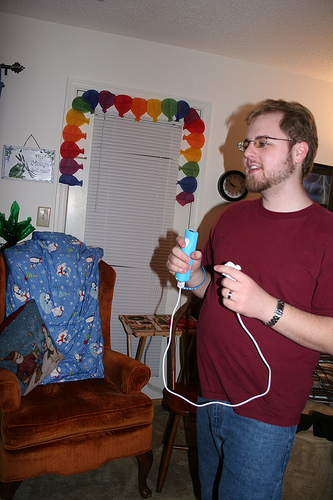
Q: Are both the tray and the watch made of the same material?
A: No, the tray is made of wood and the watch is made of metal.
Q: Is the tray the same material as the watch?
A: No, the tray is made of wood and the watch is made of metal.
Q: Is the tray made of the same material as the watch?
A: No, the tray is made of wood and the watch is made of metal.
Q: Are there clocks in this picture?
A: Yes, there is a clock.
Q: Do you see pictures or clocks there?
A: Yes, there is a clock.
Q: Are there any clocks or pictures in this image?
A: Yes, there is a clock.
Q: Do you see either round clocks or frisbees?
A: Yes, there is a round clock.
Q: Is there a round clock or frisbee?
A: Yes, there is a round clock.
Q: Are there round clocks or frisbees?
A: Yes, there is a round clock.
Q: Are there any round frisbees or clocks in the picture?
A: Yes, there is a round clock.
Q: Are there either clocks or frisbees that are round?
A: Yes, the clock is round.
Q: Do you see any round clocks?
A: Yes, there is a round clock.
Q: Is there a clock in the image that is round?
A: Yes, there is a clock that is round.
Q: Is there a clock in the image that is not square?
A: Yes, there is a round clock.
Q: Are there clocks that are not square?
A: Yes, there is a round clock.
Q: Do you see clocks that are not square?
A: Yes, there is a round clock.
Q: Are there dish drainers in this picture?
A: No, there are no dish drainers.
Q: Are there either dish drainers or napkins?
A: No, there are no dish drainers or napkins.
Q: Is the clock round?
A: Yes, the clock is round.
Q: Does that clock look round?
A: Yes, the clock is round.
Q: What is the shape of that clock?
A: The clock is round.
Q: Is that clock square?
A: No, the clock is round.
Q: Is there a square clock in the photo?
A: No, there is a clock but it is round.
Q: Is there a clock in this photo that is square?
A: No, there is a clock but it is round.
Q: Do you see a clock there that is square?
A: No, there is a clock but it is round.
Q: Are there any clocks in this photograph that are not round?
A: No, there is a clock but it is round.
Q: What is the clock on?
A: The clock is on the wall.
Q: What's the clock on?
A: The clock is on the wall.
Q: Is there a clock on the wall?
A: Yes, there is a clock on the wall.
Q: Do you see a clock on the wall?
A: Yes, there is a clock on the wall.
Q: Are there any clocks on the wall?
A: Yes, there is a clock on the wall.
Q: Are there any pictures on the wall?
A: No, there is a clock on the wall.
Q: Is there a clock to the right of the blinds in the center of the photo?
A: Yes, there is a clock to the right of the blinds.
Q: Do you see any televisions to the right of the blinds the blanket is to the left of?
A: No, there is a clock to the right of the blinds.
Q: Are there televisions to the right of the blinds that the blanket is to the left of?
A: No, there is a clock to the right of the blinds.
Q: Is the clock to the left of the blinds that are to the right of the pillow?
A: No, the clock is to the right of the blinds.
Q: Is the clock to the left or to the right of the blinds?
A: The clock is to the right of the blinds.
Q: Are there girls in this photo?
A: No, there are no girls.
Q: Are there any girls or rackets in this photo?
A: No, there are no girls or rackets.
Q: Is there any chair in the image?
A: Yes, there is a chair.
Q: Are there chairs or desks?
A: Yes, there is a chair.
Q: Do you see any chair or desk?
A: Yes, there is a chair.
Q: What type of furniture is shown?
A: The furniture is a chair.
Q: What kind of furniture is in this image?
A: The furniture is a chair.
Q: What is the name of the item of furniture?
A: The piece of furniture is a chair.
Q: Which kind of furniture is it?
A: The piece of furniture is a chair.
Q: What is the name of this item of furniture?
A: This is a chair.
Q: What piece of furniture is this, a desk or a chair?
A: This is a chair.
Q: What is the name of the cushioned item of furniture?
A: The piece of furniture is a chair.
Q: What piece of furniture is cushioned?
A: The piece of furniture is a chair.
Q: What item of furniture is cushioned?
A: The piece of furniture is a chair.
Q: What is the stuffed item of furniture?
A: The piece of furniture is a chair.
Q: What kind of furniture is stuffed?
A: The furniture is a chair.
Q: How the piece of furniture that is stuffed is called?
A: The piece of furniture is a chair.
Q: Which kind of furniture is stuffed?
A: The furniture is a chair.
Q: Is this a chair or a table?
A: This is a chair.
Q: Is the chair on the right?
A: No, the chair is on the left of the image.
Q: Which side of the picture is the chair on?
A: The chair is on the left of the image.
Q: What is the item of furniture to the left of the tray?
A: The piece of furniture is a chair.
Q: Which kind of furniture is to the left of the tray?
A: The piece of furniture is a chair.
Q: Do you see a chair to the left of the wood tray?
A: Yes, there is a chair to the left of the tray.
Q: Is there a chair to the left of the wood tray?
A: Yes, there is a chair to the left of the tray.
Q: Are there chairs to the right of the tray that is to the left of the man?
A: No, the chair is to the left of the tray.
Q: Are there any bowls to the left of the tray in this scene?
A: No, there is a chair to the left of the tray.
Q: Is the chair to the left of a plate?
A: No, the chair is to the left of the tray.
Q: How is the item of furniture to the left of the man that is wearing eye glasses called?
A: The piece of furniture is a chair.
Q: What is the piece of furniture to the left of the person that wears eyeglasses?
A: The piece of furniture is a chair.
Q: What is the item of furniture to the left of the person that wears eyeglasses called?
A: The piece of furniture is a chair.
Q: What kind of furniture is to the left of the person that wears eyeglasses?
A: The piece of furniture is a chair.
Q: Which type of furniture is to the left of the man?
A: The piece of furniture is a chair.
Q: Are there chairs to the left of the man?
A: Yes, there is a chair to the left of the man.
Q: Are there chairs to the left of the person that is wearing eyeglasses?
A: Yes, there is a chair to the left of the man.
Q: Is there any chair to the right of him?
A: No, the chair is to the left of the man.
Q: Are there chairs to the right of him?
A: No, the chair is to the left of the man.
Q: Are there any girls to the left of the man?
A: No, there is a chair to the left of the man.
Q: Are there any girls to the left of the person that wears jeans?
A: No, there is a chair to the left of the man.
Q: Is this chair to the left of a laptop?
A: No, the chair is to the left of the man.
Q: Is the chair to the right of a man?
A: No, the chair is to the left of a man.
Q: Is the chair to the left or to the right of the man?
A: The chair is to the left of the man.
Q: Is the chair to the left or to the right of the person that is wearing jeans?
A: The chair is to the left of the man.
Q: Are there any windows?
A: Yes, there is a window.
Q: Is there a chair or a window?
A: Yes, there is a window.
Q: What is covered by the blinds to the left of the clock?
A: The window is covered by the blinds.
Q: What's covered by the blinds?
A: The window is covered by the blinds.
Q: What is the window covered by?
A: The window is covered by the blinds.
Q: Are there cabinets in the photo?
A: No, there are no cabinets.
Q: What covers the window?
A: The blinds cover the window.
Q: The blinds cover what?
A: The blinds cover the window.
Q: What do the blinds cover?
A: The blinds cover the window.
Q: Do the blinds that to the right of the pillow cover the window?
A: Yes, the blinds cover the window.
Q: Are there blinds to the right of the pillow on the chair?
A: Yes, there are blinds to the right of the pillow.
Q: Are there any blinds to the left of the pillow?
A: No, the blinds are to the right of the pillow.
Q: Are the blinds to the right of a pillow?
A: Yes, the blinds are to the right of a pillow.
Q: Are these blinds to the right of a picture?
A: No, the blinds are to the right of a pillow.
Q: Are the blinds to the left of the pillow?
A: No, the blinds are to the right of the pillow.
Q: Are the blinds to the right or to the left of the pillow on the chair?
A: The blinds are to the right of the pillow.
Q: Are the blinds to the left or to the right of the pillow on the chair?
A: The blinds are to the right of the pillow.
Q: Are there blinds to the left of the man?
A: Yes, there are blinds to the left of the man.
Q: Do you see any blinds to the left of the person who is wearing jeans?
A: Yes, there are blinds to the left of the man.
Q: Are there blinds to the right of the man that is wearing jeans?
A: No, the blinds are to the left of the man.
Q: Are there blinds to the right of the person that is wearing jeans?
A: No, the blinds are to the left of the man.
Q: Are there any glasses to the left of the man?
A: No, there are blinds to the left of the man.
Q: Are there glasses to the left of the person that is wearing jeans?
A: No, there are blinds to the left of the man.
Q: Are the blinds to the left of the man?
A: Yes, the blinds are to the left of the man.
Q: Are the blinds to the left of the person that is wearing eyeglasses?
A: Yes, the blinds are to the left of the man.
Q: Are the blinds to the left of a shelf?
A: No, the blinds are to the left of the man.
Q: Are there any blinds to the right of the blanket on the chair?
A: Yes, there are blinds to the right of the blanket.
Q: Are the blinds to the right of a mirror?
A: No, the blinds are to the right of a blanket.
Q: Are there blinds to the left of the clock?
A: Yes, there are blinds to the left of the clock.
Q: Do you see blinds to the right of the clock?
A: No, the blinds are to the left of the clock.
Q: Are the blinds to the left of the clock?
A: Yes, the blinds are to the left of the clock.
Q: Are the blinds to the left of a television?
A: No, the blinds are to the left of the clock.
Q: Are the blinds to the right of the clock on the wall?
A: No, the blinds are to the left of the clock.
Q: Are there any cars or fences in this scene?
A: No, there are no fences or cars.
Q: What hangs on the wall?
A: The sign hangs on the wall.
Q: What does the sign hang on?
A: The sign hangs on the wall.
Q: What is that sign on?
A: The sign is on the wall.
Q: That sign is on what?
A: The sign is on the wall.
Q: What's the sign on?
A: The sign is on the wall.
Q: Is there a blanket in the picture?
A: Yes, there is a blanket.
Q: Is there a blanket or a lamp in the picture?
A: Yes, there is a blanket.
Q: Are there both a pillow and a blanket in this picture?
A: Yes, there are both a blanket and a pillow.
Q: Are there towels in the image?
A: No, there are no towels.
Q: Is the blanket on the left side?
A: Yes, the blanket is on the left of the image.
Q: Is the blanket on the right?
A: No, the blanket is on the left of the image.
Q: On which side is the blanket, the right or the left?
A: The blanket is on the left of the image.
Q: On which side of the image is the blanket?
A: The blanket is on the left of the image.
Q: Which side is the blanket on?
A: The blanket is on the left of the image.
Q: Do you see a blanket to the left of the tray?
A: Yes, there is a blanket to the left of the tray.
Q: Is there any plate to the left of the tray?
A: No, there is a blanket to the left of the tray.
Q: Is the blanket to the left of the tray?
A: Yes, the blanket is to the left of the tray.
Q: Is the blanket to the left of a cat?
A: No, the blanket is to the left of the tray.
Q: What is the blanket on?
A: The blanket is on the chair.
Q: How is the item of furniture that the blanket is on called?
A: The piece of furniture is a chair.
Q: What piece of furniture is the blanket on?
A: The blanket is on the chair.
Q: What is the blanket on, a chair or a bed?
A: The blanket is on a chair.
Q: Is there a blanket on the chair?
A: Yes, there is a blanket on the chair.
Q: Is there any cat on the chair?
A: No, there is a blanket on the chair.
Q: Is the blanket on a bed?
A: No, the blanket is on the chair.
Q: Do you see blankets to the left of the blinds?
A: Yes, there is a blanket to the left of the blinds.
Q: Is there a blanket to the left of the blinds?
A: Yes, there is a blanket to the left of the blinds.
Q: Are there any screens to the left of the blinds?
A: No, there is a blanket to the left of the blinds.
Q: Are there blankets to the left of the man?
A: Yes, there is a blanket to the left of the man.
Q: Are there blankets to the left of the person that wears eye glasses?
A: Yes, there is a blanket to the left of the man.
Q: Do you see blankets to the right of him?
A: No, the blanket is to the left of the man.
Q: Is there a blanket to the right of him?
A: No, the blanket is to the left of the man.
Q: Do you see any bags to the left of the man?
A: No, there is a blanket to the left of the man.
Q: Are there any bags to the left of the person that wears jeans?
A: No, there is a blanket to the left of the man.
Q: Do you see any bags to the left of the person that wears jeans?
A: No, there is a blanket to the left of the man.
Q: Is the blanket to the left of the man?
A: Yes, the blanket is to the left of the man.